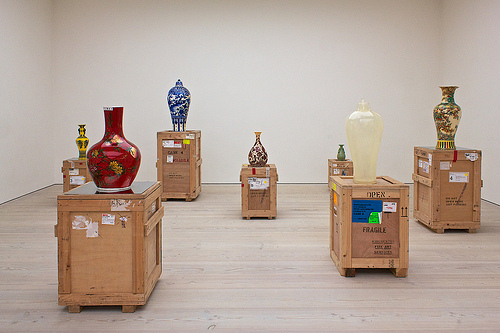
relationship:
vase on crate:
[345, 97, 384, 186] [327, 171, 412, 279]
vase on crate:
[165, 76, 192, 133] [156, 127, 203, 206]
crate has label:
[327, 171, 412, 279] [366, 209, 385, 225]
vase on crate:
[336, 141, 349, 162] [328, 158, 355, 179]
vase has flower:
[84, 103, 143, 196] [90, 148, 104, 161]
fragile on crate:
[361, 225, 390, 235] [327, 171, 412, 279]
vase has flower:
[84, 103, 143, 196] [106, 158, 120, 173]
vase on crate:
[74, 123, 91, 163] [59, 157, 93, 202]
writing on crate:
[366, 188, 389, 200] [327, 171, 412, 279]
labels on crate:
[70, 196, 132, 238] [53, 179, 166, 314]